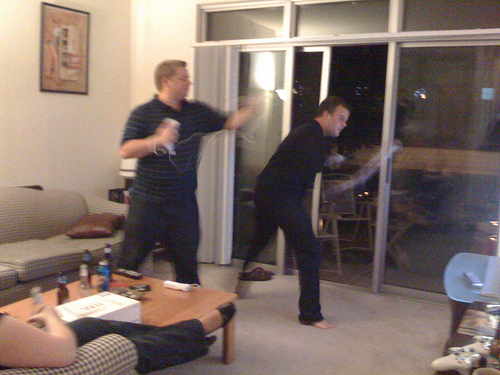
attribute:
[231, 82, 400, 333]
player — playing wii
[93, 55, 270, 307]
player — playing wii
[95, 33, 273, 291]
man — playing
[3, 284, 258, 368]
person — sitting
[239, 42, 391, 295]
door — sliding, glass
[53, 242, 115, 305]
beer bottles — brown, glass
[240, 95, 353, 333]
man — playing wii, barefoot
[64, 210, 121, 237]
pillow — brown, shiny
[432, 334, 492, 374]
contoller — white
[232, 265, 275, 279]
shoes — brown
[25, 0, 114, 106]
picture — framed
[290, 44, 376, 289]
door — open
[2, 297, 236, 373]
woman — propped up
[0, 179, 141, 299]
sofa — gray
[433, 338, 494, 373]
game controller — xbox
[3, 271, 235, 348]
table — wood, covered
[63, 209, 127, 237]
throw pillow — brown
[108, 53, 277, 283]
man — playing wii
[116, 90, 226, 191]
shirt — striped